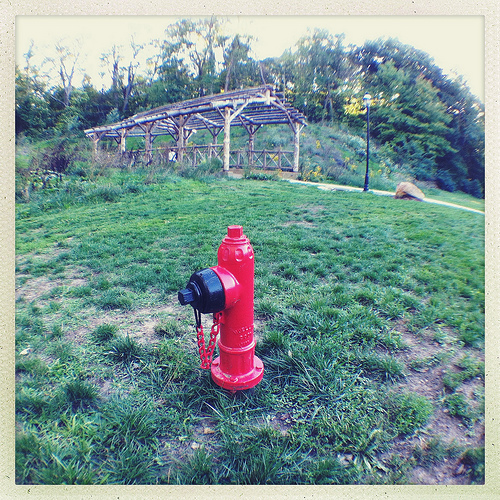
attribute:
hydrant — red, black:
[180, 223, 266, 391]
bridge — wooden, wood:
[83, 82, 308, 182]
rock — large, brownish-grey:
[394, 180, 427, 201]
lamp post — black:
[362, 92, 373, 192]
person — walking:
[167, 147, 177, 170]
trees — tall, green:
[15, 15, 483, 198]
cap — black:
[178, 267, 225, 314]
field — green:
[16, 176, 484, 485]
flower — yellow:
[314, 140, 322, 148]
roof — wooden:
[85, 84, 312, 133]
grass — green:
[99, 472, 112, 486]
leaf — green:
[24, 66, 30, 72]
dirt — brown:
[161, 412, 221, 473]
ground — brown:
[15, 265, 96, 301]